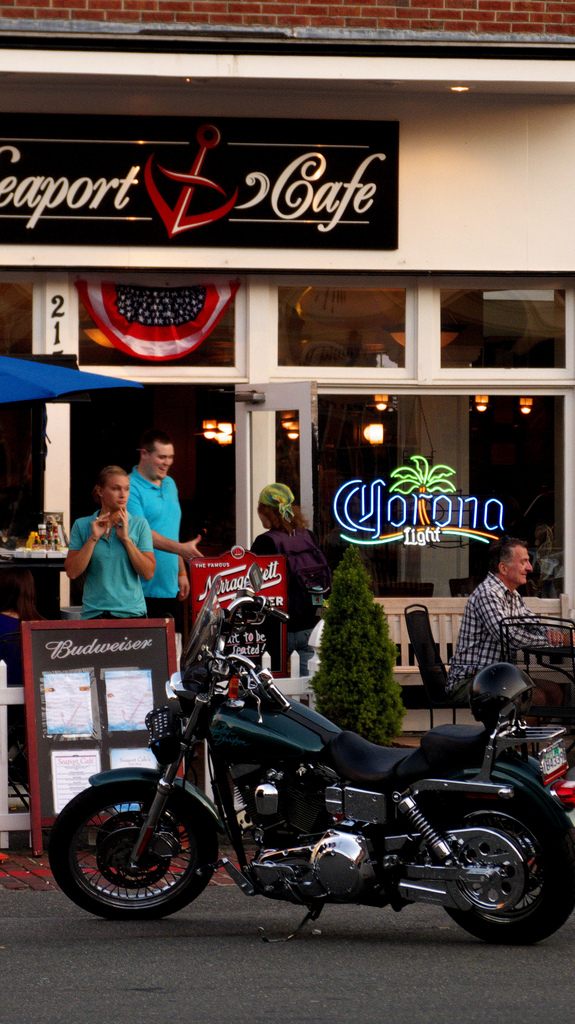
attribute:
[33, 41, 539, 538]
restaurant — Seaport cafe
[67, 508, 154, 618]
t-shirt — blue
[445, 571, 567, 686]
shirt — plaid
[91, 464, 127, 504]
hair — blonde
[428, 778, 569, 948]
wheel — round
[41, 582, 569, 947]
motorcycle — black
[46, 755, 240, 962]
wheel — round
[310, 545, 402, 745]
evergreen — small, green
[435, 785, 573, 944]
wheel — black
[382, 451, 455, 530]
tree — palm tree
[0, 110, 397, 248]
sign — Seaport Cafe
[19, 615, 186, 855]
board — menu board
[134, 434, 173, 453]
hair — brown